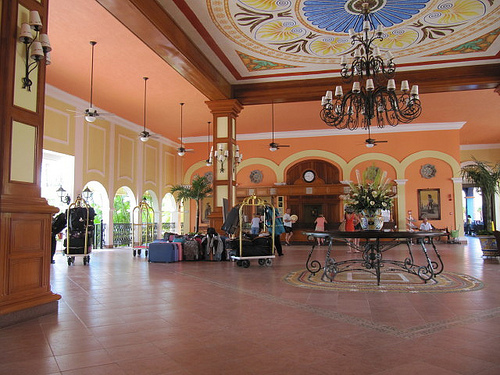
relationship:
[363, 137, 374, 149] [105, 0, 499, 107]
pendant light hangs from ceiling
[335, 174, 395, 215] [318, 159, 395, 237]
flowers in a pot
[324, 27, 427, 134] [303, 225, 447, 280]
chandelier over table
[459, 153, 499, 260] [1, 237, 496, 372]
floor plant on floor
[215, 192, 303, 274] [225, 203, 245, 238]
cart holding suitcase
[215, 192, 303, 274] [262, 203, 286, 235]
cart holding suitcase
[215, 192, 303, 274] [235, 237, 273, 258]
cart holding luggage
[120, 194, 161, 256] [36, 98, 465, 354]
wheeled cart in lobby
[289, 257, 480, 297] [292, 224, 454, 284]
design under table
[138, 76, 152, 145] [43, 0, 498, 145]
pendant light hangs on ceiling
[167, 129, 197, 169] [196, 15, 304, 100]
light hangs on ceiling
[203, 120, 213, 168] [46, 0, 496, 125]
pendant light hangs from ceiling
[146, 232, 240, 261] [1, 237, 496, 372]
suitcases on floor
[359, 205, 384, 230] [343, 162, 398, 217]
vase has plant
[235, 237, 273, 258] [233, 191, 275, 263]
luggage on cart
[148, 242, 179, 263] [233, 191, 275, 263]
luggage on cart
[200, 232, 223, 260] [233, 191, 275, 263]
suitcases on cart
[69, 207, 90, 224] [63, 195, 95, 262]
suitcases on cart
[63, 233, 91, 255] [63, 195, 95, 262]
suitcases on cart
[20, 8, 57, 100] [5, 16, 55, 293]
sconce on wall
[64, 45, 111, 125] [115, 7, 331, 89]
light hanging from ceiling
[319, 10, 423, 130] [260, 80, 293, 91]
chandelier hanging from ceiling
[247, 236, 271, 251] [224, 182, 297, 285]
luggage on cart